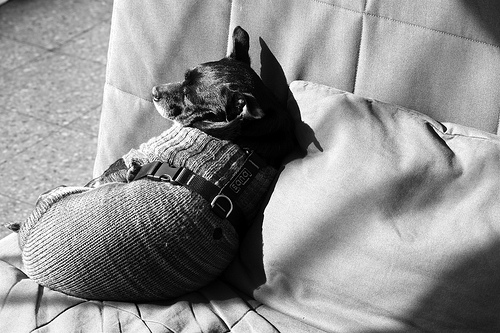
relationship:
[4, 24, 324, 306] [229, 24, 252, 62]
dog has ear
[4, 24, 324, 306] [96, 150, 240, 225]
dog wearing harness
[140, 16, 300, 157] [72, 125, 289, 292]
dog wearing sweater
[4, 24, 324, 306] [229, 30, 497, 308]
dog on couch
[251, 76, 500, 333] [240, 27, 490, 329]
pillow on couch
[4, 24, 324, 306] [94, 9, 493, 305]
dog in a chair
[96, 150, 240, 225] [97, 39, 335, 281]
harness on a dog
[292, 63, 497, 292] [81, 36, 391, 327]
pillow under dog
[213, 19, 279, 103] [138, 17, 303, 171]
ear on a dog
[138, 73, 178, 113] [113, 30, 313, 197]
muzzle on a dog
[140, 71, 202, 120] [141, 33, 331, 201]
nose on a dog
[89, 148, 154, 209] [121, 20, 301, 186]
paw on a dog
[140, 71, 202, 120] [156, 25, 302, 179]
nose of a dog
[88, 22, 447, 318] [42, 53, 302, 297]
sweater of dog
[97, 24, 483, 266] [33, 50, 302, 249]
blanket under dog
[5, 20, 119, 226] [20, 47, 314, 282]
floor next to dog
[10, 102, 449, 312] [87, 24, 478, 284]
cover on bed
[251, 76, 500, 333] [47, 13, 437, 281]
pillow on bed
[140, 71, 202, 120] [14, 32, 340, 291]
nose on dog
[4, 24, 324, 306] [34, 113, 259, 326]
dog in sweater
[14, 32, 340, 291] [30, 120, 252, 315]
dog wearing sweater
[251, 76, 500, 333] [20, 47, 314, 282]
pillow behind dog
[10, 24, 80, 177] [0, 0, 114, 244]
tiles on floor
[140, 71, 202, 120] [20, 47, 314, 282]
nose of dog